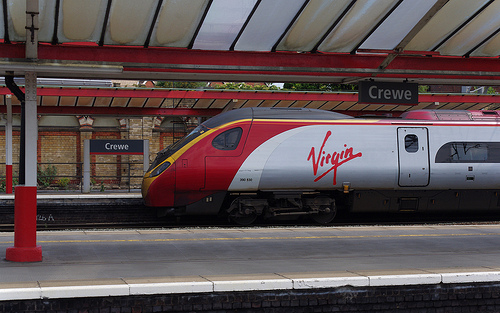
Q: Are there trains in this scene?
A: Yes, there is a train.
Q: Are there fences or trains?
A: Yes, there is a train.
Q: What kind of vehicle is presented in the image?
A: The vehicle is a train.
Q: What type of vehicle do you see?
A: The vehicle is a train.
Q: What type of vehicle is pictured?
A: The vehicle is a train.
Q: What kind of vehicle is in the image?
A: The vehicle is a train.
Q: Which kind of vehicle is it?
A: The vehicle is a train.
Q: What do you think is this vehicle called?
A: This is a train.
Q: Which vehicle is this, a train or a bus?
A: This is a train.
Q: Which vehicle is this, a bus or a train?
A: This is a train.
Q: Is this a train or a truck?
A: This is a train.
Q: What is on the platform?
A: The train is on the platform.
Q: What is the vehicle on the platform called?
A: The vehicle is a train.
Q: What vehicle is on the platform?
A: The vehicle is a train.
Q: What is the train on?
A: The train is on the platform.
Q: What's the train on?
A: The train is on the platform.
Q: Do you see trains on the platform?
A: Yes, there is a train on the platform.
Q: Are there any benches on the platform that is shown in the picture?
A: No, there is a train on the platform.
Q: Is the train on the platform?
A: Yes, the train is on the platform.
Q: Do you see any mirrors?
A: No, there are no mirrors.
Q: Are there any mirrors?
A: No, there are no mirrors.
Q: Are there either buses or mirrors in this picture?
A: No, there are no mirrors or buses.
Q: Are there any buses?
A: No, there are no buses.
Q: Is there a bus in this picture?
A: No, there are no buses.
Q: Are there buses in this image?
A: No, there are no buses.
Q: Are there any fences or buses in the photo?
A: No, there are no buses or fences.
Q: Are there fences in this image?
A: No, there are no fences.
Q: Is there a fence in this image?
A: No, there are no fences.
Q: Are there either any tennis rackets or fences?
A: No, there are no fences or tennis rackets.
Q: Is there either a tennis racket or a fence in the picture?
A: No, there are no fences or rackets.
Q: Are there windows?
A: Yes, there is a window.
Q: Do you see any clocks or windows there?
A: Yes, there is a window.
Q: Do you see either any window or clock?
A: Yes, there is a window.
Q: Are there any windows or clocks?
A: Yes, there is a window.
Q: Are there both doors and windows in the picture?
A: Yes, there are both a window and a door.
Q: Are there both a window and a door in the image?
A: Yes, there are both a window and a door.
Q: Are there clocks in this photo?
A: No, there are no clocks.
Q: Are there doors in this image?
A: Yes, there is a door.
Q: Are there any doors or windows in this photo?
A: Yes, there is a door.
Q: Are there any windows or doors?
A: Yes, there is a door.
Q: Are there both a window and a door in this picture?
A: Yes, there are both a door and a window.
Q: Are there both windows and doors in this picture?
A: Yes, there are both a door and windows.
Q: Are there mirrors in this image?
A: No, there are no mirrors.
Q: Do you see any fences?
A: No, there are no fences.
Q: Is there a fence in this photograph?
A: No, there are no fences.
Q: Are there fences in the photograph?
A: No, there are no fences.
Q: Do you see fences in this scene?
A: No, there are no fences.